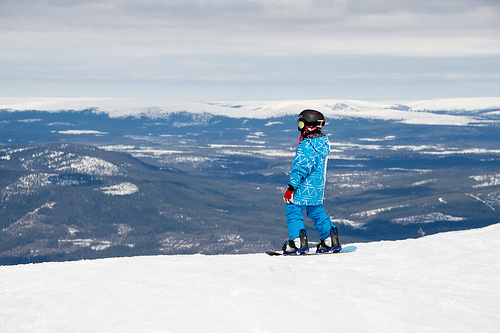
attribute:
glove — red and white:
[281, 183, 297, 205]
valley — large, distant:
[0, 79, 252, 274]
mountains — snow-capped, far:
[10, 92, 499, 127]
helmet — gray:
[299, 109, 331, 126]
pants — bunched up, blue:
[266, 184, 361, 261]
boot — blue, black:
[282, 233, 315, 254]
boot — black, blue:
[317, 234, 334, 251]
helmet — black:
[299, 105, 324, 135]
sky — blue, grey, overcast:
[0, 0, 499, 104]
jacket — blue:
[303, 137, 323, 198]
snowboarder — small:
[286, 120, 332, 250]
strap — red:
[303, 130, 316, 138]